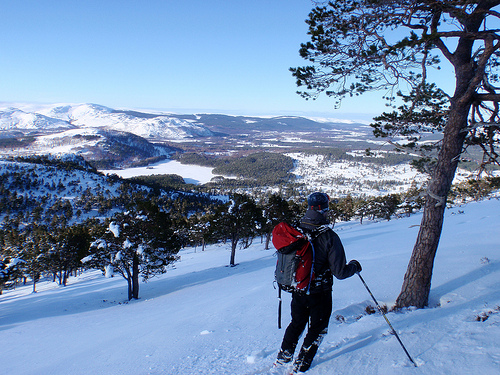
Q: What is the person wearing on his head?
A: A hat.